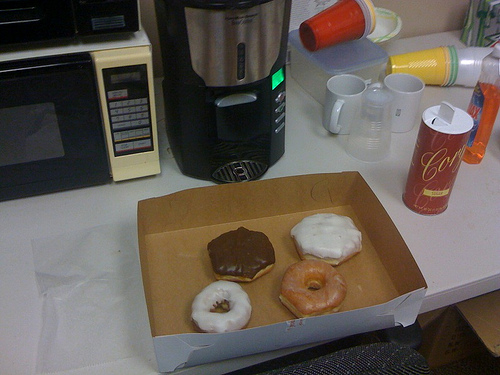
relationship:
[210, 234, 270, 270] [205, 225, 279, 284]
chocolate on top of donut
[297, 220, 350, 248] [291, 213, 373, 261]
icing on top of donut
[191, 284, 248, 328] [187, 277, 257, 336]
vanilla frosting on top of donut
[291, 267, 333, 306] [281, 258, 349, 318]
plain glazing on top of donut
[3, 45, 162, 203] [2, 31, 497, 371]
microwave on top of counter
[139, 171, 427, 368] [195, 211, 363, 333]
box of donuts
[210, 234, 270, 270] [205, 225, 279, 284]
chocolate icing on top of hexagon shaped donut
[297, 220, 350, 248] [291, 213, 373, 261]
vanilla icing on top of hexagon shaped donut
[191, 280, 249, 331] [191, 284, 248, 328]
vanilla frosting on top of round donut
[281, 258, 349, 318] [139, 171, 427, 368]
glazed donut in box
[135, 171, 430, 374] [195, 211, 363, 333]
box full of donuts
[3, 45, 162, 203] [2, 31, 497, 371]
microwave on counter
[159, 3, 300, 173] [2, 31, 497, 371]
coffee pot on counter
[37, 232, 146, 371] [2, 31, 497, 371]
wax paper on counter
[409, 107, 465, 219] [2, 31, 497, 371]
coffee creamer on counter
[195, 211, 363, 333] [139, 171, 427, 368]
four donuts left in box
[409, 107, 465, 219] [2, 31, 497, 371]
container of sugar on counter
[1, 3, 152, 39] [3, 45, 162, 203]
microwave on top of another microwave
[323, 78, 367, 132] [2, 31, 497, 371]
white mug on counter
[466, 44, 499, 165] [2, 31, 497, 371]
dish soap bottle on counter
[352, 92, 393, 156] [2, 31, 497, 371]
plastic cups on counter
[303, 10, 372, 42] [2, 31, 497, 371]
plastic cups on counter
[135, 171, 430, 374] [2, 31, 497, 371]
box under table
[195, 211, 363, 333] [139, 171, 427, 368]
four donuts inside box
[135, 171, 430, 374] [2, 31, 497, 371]
box on counter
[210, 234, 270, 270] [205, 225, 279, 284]
chocolate icing on donut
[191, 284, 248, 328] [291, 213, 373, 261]
vanilla frosting on top of donut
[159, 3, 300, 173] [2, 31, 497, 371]
coffee maker on counter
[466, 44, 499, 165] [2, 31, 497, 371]
dishwashing soap on counter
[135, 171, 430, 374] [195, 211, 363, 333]
box filled with donuts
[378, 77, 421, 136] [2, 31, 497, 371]
white coffee cup on counter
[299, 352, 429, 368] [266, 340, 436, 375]
fabric on top of bench